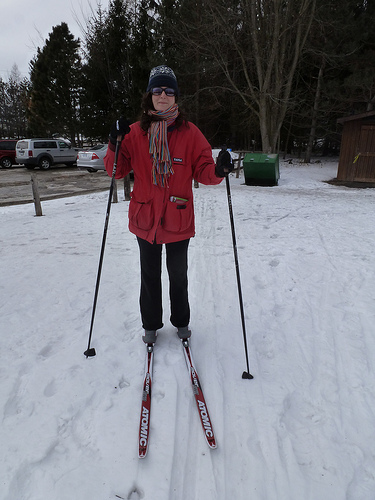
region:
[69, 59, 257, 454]
woman in skis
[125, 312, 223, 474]
skis with red trim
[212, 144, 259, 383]
hand holding ski pole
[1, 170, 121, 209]
split-log style fence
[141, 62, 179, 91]
black knit hat with snowflake design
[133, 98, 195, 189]
colorful striped scarf with fringe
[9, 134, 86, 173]
parked white SUV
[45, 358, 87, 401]
footprint in the snow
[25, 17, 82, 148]
pine tree in front of grey winter sky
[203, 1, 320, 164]
tree with no leaves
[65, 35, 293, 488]
a woman wearing skis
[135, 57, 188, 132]
a woman wearing sunglasses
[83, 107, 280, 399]
a person holding two ski poles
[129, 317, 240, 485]
two red and white skis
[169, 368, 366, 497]
ski tracks in the snow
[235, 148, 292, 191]
a green garbage can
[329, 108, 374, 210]
a brown wooden cabin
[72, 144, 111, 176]
a silver car parked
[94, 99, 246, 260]
a large red winter coat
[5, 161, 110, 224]
a wooden fence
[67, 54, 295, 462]
Woman in a red coat skiing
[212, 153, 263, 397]
Ski pole in a persons left hand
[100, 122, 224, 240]
Red coat on a person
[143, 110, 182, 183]
Multi-colored scarf on a persons neck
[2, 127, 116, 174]
Three automobiles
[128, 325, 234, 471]
Skis on a persons feet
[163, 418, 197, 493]
Tracks in the snow from skis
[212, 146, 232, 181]
Hand wearing a black glove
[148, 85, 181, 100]
Sunglasses on someone's face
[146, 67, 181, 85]
Ski cap on a woman's head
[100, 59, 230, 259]
Woman clothing adequate weather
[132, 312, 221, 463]
Atomic ski brand tip ski's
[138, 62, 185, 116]
Sunglasses not goggles eyes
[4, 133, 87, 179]
Silver SUV parking lot left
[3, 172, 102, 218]
Wooden fence surrounds yard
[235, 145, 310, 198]
Green trash dumpster behind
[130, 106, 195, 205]
Colorful knit scarf red jacket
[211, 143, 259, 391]
Gloved hand grips ski pole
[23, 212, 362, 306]
Foot and ski prints snow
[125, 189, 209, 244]
Pockets bulge necessary items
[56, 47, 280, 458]
a woman on cross country skis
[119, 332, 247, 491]
the woman's red skis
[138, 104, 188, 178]
a colorful scarf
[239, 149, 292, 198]
a green dumpster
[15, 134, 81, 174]
a grey SUV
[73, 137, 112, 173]
a grey car next to the grey SUV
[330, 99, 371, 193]
a small wooden shed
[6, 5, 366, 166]
the woods in the background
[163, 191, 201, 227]
the pocket with a book in side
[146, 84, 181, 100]
the woman's dark sunglasses